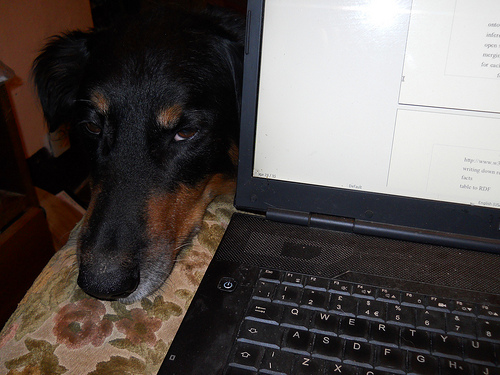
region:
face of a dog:
[21, 1, 240, 320]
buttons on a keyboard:
[261, 257, 497, 369]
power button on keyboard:
[216, 268, 240, 300]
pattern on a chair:
[21, 306, 148, 368]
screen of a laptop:
[267, 60, 480, 186]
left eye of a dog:
[156, 100, 211, 151]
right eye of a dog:
[76, 93, 116, 156]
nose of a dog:
[63, 263, 153, 307]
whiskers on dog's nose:
[148, 235, 198, 290]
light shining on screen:
[351, 0, 419, 40]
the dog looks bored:
[59, 31, 227, 295]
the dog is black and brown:
[57, 44, 215, 314]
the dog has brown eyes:
[170, 125, 197, 142]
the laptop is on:
[246, 17, 492, 204]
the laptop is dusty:
[209, 209, 459, 344]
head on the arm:
[72, 80, 217, 327]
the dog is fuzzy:
[67, 20, 249, 268]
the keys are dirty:
[238, 280, 481, 359]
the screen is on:
[237, 13, 477, 242]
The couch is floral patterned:
[18, 233, 200, 353]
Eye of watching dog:
[164, 120, 208, 147]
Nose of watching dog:
[70, 248, 147, 297]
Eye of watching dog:
[76, 102, 110, 137]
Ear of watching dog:
[28, 27, 83, 137]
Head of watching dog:
[29, 25, 221, 305]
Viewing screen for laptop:
[230, 2, 498, 249]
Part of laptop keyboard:
[233, 215, 498, 372]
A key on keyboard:
[283, 324, 313, 356]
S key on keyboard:
[313, 332, 347, 367]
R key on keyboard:
[371, 319, 403, 351]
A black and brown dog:
[13, 2, 243, 302]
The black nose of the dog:
[78, 252, 150, 307]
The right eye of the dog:
[159, 122, 208, 147]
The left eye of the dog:
[73, 107, 113, 142]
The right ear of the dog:
[10, 34, 105, 127]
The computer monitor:
[246, 0, 498, 227]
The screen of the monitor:
[242, 2, 498, 224]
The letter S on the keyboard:
[319, 331, 339, 355]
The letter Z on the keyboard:
[300, 352, 321, 373]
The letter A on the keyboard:
[283, 325, 306, 347]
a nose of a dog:
[36, 215, 196, 320]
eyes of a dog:
[53, 112, 233, 163]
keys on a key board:
[203, 255, 471, 352]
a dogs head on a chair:
[54, 43, 259, 329]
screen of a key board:
[226, 35, 493, 253]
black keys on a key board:
[201, 285, 484, 370]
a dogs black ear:
[26, 19, 142, 128]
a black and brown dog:
[56, 5, 246, 297]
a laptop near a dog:
[14, 26, 492, 326]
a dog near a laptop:
[56, 0, 451, 308]